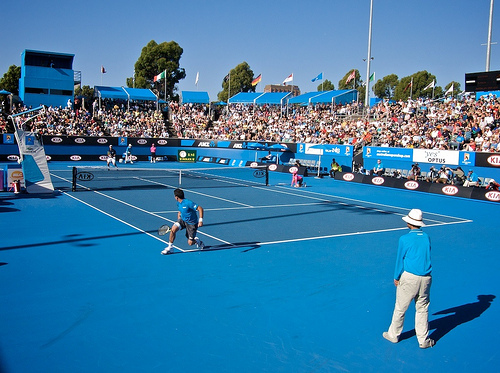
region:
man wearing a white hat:
[393, 207, 435, 349]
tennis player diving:
[155, 185, 205, 255]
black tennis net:
[67, 160, 272, 186]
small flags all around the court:
[94, 60, 464, 103]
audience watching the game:
[259, 102, 411, 149]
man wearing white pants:
[381, 207, 435, 347]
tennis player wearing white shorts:
[102, 142, 119, 169]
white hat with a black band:
[402, 207, 424, 229]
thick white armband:
[196, 215, 202, 223]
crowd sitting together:
[407, 114, 452, 143]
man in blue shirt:
[385, 205, 435, 354]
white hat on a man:
[387, 205, 438, 355]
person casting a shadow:
[386, 203, 496, 354]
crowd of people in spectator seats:
[227, 84, 499, 157]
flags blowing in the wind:
[146, 56, 362, 97]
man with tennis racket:
[151, 182, 216, 264]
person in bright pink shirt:
[146, 140, 160, 161]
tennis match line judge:
[287, 154, 310, 191]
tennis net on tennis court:
[63, 153, 277, 194]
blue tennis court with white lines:
[37, 137, 473, 256]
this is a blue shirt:
[389, 223, 446, 286]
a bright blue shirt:
[168, 184, 211, 229]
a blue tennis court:
[25, 145, 474, 300]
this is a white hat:
[393, 197, 445, 233]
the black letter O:
[424, 155, 433, 165]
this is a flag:
[281, 73, 298, 97]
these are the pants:
[388, 260, 446, 360]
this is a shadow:
[394, 278, 499, 355]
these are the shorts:
[167, 210, 206, 240]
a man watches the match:
[382, 205, 436, 351]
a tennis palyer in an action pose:
[153, 186, 211, 259]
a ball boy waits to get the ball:
[285, 165, 308, 191]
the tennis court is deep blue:
[9, 165, 477, 254]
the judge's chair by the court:
[8, 98, 61, 196]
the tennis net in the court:
[63, 155, 281, 191]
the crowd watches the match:
[2, 90, 499, 158]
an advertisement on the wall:
[437, 181, 460, 196]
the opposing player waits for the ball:
[101, 143, 124, 174]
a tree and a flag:
[134, 39, 189, 114]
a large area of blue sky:
[0, 0, 499, 102]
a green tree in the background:
[125, 38, 187, 103]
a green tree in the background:
[0, 63, 22, 96]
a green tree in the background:
[216, 60, 256, 102]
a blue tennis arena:
[0, 48, 499, 371]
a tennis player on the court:
[160, 188, 206, 255]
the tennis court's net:
[72, 165, 268, 192]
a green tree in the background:
[316, 77, 335, 91]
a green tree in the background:
[392, 69, 436, 101]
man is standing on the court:
[384, 207, 433, 348]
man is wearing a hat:
[384, 207, 436, 347]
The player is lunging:
[153, 187, 210, 257]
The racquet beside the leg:
[156, 221, 171, 239]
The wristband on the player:
[199, 216, 204, 221]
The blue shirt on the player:
[174, 198, 202, 223]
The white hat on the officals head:
[399, 205, 427, 227]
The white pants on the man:
[387, 268, 432, 344]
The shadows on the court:
[398, 291, 496, 344]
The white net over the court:
[73, 162, 266, 191]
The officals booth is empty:
[12, 104, 53, 192]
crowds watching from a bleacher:
[474, 93, 499, 166]